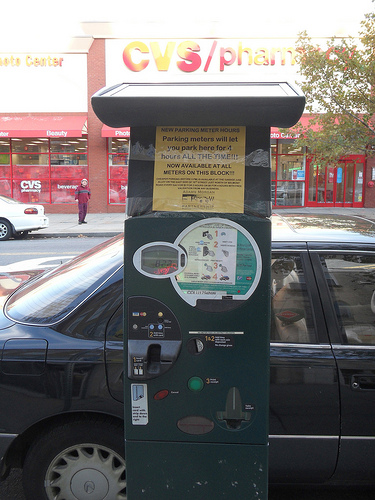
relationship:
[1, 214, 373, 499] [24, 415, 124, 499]
car has wheel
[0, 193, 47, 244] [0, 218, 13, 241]
car has wheel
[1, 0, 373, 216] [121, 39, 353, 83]
store has sign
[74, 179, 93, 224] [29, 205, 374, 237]
man on sidewalk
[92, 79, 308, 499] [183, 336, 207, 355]
parking meter has coin slot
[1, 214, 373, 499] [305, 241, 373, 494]
car has door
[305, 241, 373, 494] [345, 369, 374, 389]
door has handle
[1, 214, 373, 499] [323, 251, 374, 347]
car has window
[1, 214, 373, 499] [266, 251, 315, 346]
car has window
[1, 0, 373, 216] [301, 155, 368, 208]
store has door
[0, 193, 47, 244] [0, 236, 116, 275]
car parked on street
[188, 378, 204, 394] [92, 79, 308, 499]
button on parking meter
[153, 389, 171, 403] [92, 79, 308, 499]
button on parking meter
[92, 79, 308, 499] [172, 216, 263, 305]
parking meter has instructions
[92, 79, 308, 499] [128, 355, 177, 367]
parking meter has money slot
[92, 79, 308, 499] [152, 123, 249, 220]
parking meter has sign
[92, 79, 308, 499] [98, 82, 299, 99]
parking meter has solar panel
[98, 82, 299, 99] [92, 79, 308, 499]
solar panel on top of parking meter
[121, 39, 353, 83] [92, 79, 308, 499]
sign behind parking meter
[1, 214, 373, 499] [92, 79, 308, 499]
car behind parking meter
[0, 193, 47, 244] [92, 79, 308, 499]
car behind parking meter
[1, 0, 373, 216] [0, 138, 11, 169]
store has window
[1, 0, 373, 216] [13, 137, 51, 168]
store has window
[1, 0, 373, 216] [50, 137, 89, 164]
store has window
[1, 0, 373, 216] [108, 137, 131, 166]
store has window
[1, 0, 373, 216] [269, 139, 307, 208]
store has window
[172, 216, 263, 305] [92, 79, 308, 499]
instructions are on parking meter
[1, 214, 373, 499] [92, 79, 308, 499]
car parked at parking meter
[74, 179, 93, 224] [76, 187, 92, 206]
man wearing shirt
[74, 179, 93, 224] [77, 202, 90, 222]
man wearing pants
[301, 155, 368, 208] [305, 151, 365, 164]
door has frame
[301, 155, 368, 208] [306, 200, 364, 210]
door has frame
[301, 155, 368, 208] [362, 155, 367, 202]
door has frame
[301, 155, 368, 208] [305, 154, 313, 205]
door has frame